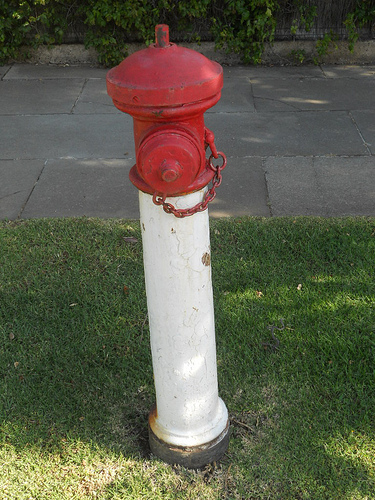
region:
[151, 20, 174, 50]
the bolt on the fire hydrant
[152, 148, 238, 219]
a red chain on the fire hydrant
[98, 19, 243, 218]
a red fire hydrant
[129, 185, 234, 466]
the base of a fire hydrant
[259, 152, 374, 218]
a gray slab of cement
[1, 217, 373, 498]
a patch of green grass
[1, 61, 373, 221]
a gray cement sidewalk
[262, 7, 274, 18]
a green leaf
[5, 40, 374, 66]
a gray cement curb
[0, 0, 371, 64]
green leafy plants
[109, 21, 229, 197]
red part of hydrant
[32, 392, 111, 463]
green grass next to hydrant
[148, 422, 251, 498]
dark base of hydrant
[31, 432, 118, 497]
light hitting the grass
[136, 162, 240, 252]
red chain around hydrant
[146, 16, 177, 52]
red tip of hydrant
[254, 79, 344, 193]
gray sidewalk next to grass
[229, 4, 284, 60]
green leaves on wall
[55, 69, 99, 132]
crack on the cement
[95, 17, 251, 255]
red hydrant and white pole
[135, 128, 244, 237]
red chain of fire hydrant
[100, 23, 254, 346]
fire hydrant is red and white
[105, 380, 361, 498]
fire hydrant is in the grass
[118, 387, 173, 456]
rust on the fire hydrant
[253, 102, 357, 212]
the sidewalk is grey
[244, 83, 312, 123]
crack in the sidewalk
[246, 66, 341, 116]
light shadow on the sidewalk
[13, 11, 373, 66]
bushes along the sidewalk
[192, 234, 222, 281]
paint missing from the fire hydrant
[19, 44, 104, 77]
curb of the sidewalk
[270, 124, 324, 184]
part of a floor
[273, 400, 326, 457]
part of a green ground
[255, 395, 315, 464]
part of a shade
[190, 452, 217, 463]
base of a post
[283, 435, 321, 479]
part of some grass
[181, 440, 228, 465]
base of a post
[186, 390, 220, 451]
edge of a post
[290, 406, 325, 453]
part of a ground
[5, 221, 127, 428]
Patch to green grass next to sidewalk.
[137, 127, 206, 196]
Red painted nob on fire hydrant.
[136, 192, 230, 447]
White painted post for fire hydrant.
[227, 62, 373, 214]
Concret blocked sidewalk.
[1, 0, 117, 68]
Vegetation growing on wall.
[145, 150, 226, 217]
Red painted chain on fire hydrant.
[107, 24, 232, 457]
Red and white painted fire hydrant.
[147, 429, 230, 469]
Concret base to fire hydrant.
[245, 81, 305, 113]
Cracks in concrete sidewalk block.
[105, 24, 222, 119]
Top section to fire hydrant.